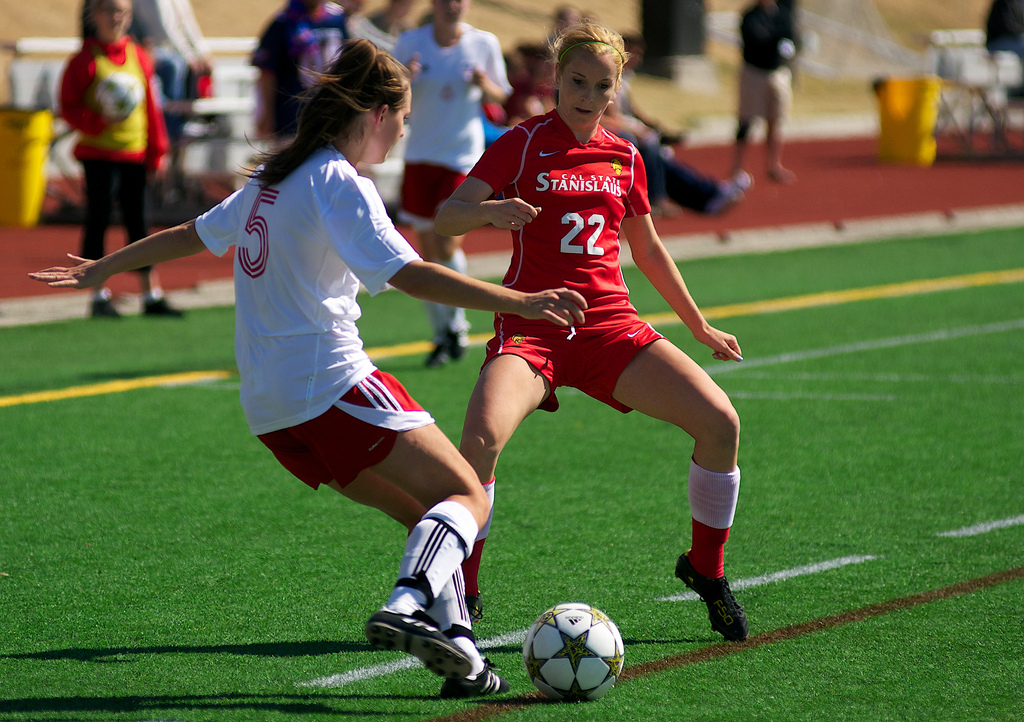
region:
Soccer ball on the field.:
[493, 557, 607, 690]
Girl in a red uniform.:
[435, 111, 825, 514]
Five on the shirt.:
[198, 97, 358, 306]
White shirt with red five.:
[125, 92, 416, 393]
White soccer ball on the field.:
[501, 535, 716, 720]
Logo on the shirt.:
[464, 135, 756, 304]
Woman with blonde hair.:
[479, 29, 676, 197]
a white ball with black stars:
[515, 584, 651, 702]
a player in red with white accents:
[455, 13, 789, 656]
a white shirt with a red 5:
[174, 124, 432, 423]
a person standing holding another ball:
[51, 0, 195, 346]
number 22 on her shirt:
[558, 209, 613, 267]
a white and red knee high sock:
[651, 456, 759, 600]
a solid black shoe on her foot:
[669, 549, 768, 636]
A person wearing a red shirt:
[431, 25, 855, 617]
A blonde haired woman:
[422, 23, 816, 654]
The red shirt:
[470, 120, 660, 299]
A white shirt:
[182, 153, 407, 391]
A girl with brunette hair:
[153, 23, 586, 669]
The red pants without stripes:
[491, 263, 669, 397]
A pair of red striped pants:
[220, 368, 414, 479]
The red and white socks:
[438, 469, 761, 594]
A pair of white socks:
[362, 472, 487, 632]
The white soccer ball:
[501, 583, 658, 691]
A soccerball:
[514, 589, 629, 719]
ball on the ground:
[482, 562, 666, 712]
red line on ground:
[844, 554, 985, 654]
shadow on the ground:
[87, 591, 240, 713]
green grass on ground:
[800, 395, 960, 495]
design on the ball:
[486, 565, 645, 720]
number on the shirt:
[174, 145, 337, 357]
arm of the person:
[420, 130, 537, 273]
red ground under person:
[774, 143, 937, 243]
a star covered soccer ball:
[525, 595, 628, 700]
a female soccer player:
[431, 20, 757, 641]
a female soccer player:
[26, 29, 584, 693]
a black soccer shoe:
[671, 545, 748, 643]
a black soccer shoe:
[468, 593, 482, 614]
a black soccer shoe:
[362, 599, 474, 680]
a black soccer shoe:
[437, 658, 515, 697]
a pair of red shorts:
[487, 311, 665, 411]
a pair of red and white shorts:
[248, 367, 435, 494]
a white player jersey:
[193, 152, 415, 440]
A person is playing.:
[363, 20, 775, 656]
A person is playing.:
[56, 39, 490, 679]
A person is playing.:
[384, 7, 501, 378]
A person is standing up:
[49, 1, 231, 322]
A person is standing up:
[264, 4, 345, 216]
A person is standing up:
[386, 4, 522, 347]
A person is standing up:
[81, 62, 521, 679]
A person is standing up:
[430, 27, 778, 654]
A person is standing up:
[732, 0, 805, 197]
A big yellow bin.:
[863, 70, 934, 182]